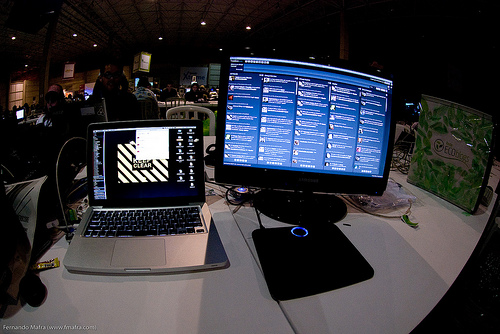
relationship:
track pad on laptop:
[106, 236, 167, 269] [61, 118, 232, 275]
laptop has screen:
[70, 118, 235, 283] [86, 125, 203, 203]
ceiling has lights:
[2, 3, 497, 71] [4, 9, 313, 50]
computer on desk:
[214, 47, 404, 223] [349, 197, 492, 320]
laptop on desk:
[61, 118, 232, 275] [349, 197, 492, 320]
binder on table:
[399, 94, 492, 219] [204, 134, 499, 333]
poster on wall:
[132, 47, 154, 79] [1, 47, 225, 113]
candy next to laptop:
[28, 252, 73, 275] [78, 98, 248, 289]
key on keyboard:
[105, 209, 115, 218] [73, 200, 223, 260]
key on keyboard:
[118, 207, 128, 216] [79, 200, 221, 245]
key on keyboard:
[83, 225, 93, 238] [86, 212, 202, 232]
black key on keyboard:
[158, 227, 169, 236] [83, 209, 205, 237]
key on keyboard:
[90, 221, 122, 231] [76, 189, 211, 244]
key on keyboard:
[164, 212, 171, 222] [79, 207, 203, 238]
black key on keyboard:
[185, 225, 195, 232] [81, 206, 207, 237]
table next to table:
[204, 123, 498, 332] [0, 159, 300, 332]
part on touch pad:
[291, 224, 308, 236] [251, 221, 374, 301]